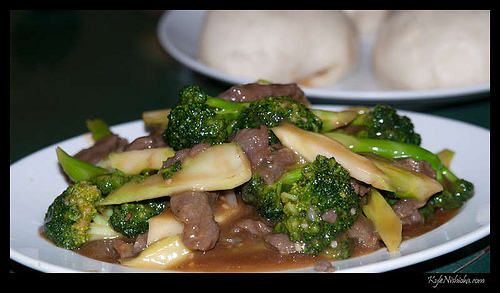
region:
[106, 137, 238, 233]
This is a beef dish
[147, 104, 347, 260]
The dish is mongolian beef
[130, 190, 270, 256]
The beef is brown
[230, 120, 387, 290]
This is broccoli that is green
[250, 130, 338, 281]
The broccoli is green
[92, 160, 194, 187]
These are broccoli stems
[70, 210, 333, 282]
This is brown sauce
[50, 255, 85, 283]
This is a white plate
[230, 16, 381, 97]
These are bowls of rice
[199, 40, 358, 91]
The rice is white and pure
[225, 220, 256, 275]
part of a soup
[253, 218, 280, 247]
part of a soup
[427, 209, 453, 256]
dge of a plate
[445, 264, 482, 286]
part of a graphic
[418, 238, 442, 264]
dge of a plate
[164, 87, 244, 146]
chopped green broccoli floret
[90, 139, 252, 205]
cut beige bamboo shoot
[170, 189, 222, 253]
sauteed strips of beef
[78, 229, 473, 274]
brown sauce over food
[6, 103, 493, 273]
round white ceramic plate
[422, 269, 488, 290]
watermark in corner of photo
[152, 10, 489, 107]
plate of dough balls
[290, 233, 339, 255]
chopped white garlic on broccoli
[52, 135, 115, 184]
cut green broccoli stem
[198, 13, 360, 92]
white folded dough ball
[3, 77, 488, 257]
a plate of food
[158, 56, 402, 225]
the broccoli is covered in sauce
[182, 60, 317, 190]
the meat is brown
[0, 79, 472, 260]
the plate is white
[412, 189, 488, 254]
the plate is reflecting objects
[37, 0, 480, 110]
the background is a little blurry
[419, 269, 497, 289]
a signature on the bottom right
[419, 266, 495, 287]
the letters are white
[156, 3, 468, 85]
dumplings on a plate in the background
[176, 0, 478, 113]
the dumplings are white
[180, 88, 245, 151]
brocolli on top of plate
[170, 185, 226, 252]
beef in a dish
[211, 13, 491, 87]
white rolls on a plate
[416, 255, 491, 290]
name of the photographer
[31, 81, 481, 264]
beef and veggie dinner on plate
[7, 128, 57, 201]
edge of white plate on table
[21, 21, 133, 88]
black dinner table in photo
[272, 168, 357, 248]
brocolli on a plate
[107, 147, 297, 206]
onion in a beef dinner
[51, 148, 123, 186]
green pepper in a beef dinner